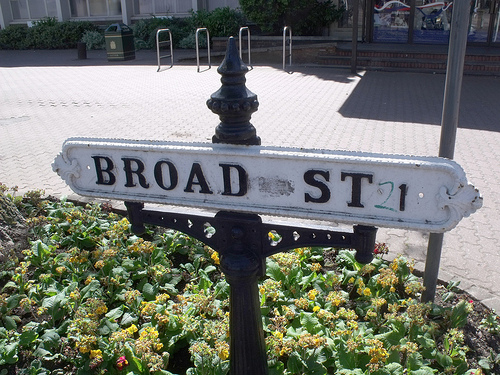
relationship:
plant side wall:
[33, 17, 72, 44] [1, 2, 341, 59]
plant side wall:
[238, 0, 327, 32] [1, 2, 341, 59]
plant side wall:
[195, 8, 233, 33] [1, 2, 341, 59]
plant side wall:
[183, 32, 208, 51] [1, 2, 341, 59]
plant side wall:
[78, 32, 100, 47] [1, 2, 341, 59]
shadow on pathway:
[78, 37, 430, 123] [6, 30, 478, 122]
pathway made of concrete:
[2, 67, 499, 288] [3, 43, 75, 65]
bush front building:
[21, 14, 83, 51] [1, 1, 213, 55]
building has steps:
[250, 1, 499, 73] [314, 40, 499, 77]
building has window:
[250, 1, 499, 69] [413, 0, 452, 44]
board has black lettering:
[48, 136, 486, 234] [90, 154, 247, 197]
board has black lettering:
[48, 136, 486, 234] [300, 167, 408, 211]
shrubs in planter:
[0, 3, 420, 54] [1, 39, 331, 60]